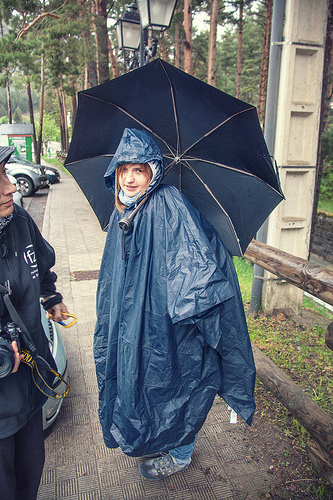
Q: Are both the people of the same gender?
A: No, they are both male and female.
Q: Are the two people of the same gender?
A: No, they are both male and female.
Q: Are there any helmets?
A: No, there are no helmets.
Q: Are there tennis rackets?
A: No, there are no tennis rackets.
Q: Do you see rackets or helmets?
A: No, there are no rackets or helmets.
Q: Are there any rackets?
A: No, there are no rackets.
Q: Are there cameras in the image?
A: Yes, there is a camera.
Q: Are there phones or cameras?
A: Yes, there is a camera.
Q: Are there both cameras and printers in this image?
A: No, there is a camera but no printers.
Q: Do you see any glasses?
A: No, there are no glasses.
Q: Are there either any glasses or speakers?
A: No, there are no glasses or speakers.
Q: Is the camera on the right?
A: No, the camera is on the left of the image.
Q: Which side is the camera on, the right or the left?
A: The camera is on the left of the image.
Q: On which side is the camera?
A: The camera is on the left of the image.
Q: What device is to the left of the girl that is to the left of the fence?
A: The device is a camera.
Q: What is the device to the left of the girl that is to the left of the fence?
A: The device is a camera.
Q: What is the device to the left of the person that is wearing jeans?
A: The device is a camera.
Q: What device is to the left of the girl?
A: The device is a camera.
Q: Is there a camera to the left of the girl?
A: Yes, there is a camera to the left of the girl.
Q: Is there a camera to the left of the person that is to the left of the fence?
A: Yes, there is a camera to the left of the girl.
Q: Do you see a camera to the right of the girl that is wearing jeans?
A: No, the camera is to the left of the girl.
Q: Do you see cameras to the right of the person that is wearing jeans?
A: No, the camera is to the left of the girl.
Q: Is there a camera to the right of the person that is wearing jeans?
A: No, the camera is to the left of the girl.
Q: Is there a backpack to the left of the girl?
A: No, there is a camera to the left of the girl.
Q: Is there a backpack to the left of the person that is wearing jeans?
A: No, there is a camera to the left of the girl.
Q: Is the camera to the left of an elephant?
A: No, the camera is to the left of a girl.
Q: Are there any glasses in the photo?
A: No, there are no glasses.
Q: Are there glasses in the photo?
A: No, there are no glasses.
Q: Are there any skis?
A: No, there are no skis.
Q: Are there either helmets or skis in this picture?
A: No, there are no skis or helmets.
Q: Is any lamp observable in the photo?
A: Yes, there is a lamp.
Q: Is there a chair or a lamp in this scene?
A: Yes, there is a lamp.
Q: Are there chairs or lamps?
A: Yes, there is a lamp.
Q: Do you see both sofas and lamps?
A: No, there is a lamp but no sofas.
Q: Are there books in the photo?
A: No, there are no books.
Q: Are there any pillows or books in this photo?
A: No, there are no books or pillows.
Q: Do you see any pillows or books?
A: No, there are no books or pillows.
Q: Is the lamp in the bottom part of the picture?
A: No, the lamp is in the top of the image.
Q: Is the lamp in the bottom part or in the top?
A: The lamp is in the top of the image.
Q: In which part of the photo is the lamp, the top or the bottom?
A: The lamp is in the top of the image.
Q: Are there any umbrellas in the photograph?
A: Yes, there is an umbrella.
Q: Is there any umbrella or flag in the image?
A: Yes, there is an umbrella.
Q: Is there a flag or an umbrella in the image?
A: Yes, there is an umbrella.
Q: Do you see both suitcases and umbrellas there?
A: No, there is an umbrella but no suitcases.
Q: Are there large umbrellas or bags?
A: Yes, there is a large umbrella.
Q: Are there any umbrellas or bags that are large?
A: Yes, the umbrella is large.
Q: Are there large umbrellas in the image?
A: Yes, there is a large umbrella.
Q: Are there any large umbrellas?
A: Yes, there is a large umbrella.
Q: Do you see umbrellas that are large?
A: Yes, there is a large umbrella.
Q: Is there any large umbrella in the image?
A: Yes, there is a large umbrella.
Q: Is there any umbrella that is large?
A: Yes, there is an umbrella that is large.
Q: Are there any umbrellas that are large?
A: Yes, there is an umbrella that is large.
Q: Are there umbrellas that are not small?
A: Yes, there is a large umbrella.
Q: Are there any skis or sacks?
A: No, there are no skis or sacks.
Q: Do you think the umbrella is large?
A: Yes, the umbrella is large.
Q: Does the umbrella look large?
A: Yes, the umbrella is large.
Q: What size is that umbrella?
A: The umbrella is large.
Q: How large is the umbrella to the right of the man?
A: The umbrella is large.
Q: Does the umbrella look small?
A: No, the umbrella is large.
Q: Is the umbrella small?
A: No, the umbrella is large.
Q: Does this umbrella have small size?
A: No, the umbrella is large.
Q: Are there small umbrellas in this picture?
A: No, there is an umbrella but it is large.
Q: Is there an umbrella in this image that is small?
A: No, there is an umbrella but it is large.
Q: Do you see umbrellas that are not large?
A: No, there is an umbrella but it is large.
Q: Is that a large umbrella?
A: Yes, that is a large umbrella.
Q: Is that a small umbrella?
A: No, that is a large umbrella.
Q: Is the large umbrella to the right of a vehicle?
A: Yes, the umbrella is to the right of a vehicle.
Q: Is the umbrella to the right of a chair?
A: No, the umbrella is to the right of a vehicle.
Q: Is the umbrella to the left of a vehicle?
A: No, the umbrella is to the right of a vehicle.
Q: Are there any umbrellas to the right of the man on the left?
A: Yes, there is an umbrella to the right of the man.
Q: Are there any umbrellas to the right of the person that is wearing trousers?
A: Yes, there is an umbrella to the right of the man.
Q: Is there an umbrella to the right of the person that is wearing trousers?
A: Yes, there is an umbrella to the right of the man.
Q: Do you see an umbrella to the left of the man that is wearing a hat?
A: No, the umbrella is to the right of the man.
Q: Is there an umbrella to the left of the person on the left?
A: No, the umbrella is to the right of the man.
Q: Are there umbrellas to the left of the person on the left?
A: No, the umbrella is to the right of the man.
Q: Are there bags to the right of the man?
A: No, there is an umbrella to the right of the man.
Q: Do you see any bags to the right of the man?
A: No, there is an umbrella to the right of the man.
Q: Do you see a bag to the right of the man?
A: No, there is an umbrella to the right of the man.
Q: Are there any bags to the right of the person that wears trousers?
A: No, there is an umbrella to the right of the man.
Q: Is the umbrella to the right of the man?
A: Yes, the umbrella is to the right of the man.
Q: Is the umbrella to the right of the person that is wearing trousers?
A: Yes, the umbrella is to the right of the man.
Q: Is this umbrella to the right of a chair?
A: No, the umbrella is to the right of the man.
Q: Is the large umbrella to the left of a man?
A: No, the umbrella is to the right of a man.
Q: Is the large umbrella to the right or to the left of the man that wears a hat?
A: The umbrella is to the right of the man.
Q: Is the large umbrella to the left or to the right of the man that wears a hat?
A: The umbrella is to the right of the man.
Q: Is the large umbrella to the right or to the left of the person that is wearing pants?
A: The umbrella is to the right of the man.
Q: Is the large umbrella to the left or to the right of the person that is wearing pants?
A: The umbrella is to the right of the man.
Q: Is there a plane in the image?
A: No, there are no airplanes.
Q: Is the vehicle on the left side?
A: Yes, the vehicle is on the left of the image.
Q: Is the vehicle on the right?
A: No, the vehicle is on the left of the image.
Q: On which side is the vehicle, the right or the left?
A: The vehicle is on the left of the image.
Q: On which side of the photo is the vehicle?
A: The vehicle is on the left of the image.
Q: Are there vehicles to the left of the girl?
A: Yes, there is a vehicle to the left of the girl.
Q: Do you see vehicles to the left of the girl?
A: Yes, there is a vehicle to the left of the girl.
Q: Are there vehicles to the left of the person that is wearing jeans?
A: Yes, there is a vehicle to the left of the girl.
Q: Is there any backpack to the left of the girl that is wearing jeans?
A: No, there is a vehicle to the left of the girl.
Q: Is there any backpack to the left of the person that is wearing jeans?
A: No, there is a vehicle to the left of the girl.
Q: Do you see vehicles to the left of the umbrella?
A: Yes, there is a vehicle to the left of the umbrella.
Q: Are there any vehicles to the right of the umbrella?
A: No, the vehicle is to the left of the umbrella.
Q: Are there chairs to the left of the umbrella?
A: No, there is a vehicle to the left of the umbrella.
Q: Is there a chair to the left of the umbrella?
A: No, there is a vehicle to the left of the umbrella.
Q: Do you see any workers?
A: No, there are no workers.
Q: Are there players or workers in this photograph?
A: No, there are no workers or players.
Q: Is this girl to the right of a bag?
A: No, the girl is to the right of a vehicle.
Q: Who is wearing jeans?
A: The girl is wearing jeans.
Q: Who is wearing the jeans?
A: The girl is wearing jeans.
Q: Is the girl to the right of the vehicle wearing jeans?
A: Yes, the girl is wearing jeans.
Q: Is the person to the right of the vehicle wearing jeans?
A: Yes, the girl is wearing jeans.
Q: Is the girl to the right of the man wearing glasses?
A: No, the girl is wearing jeans.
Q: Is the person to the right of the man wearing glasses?
A: No, the girl is wearing jeans.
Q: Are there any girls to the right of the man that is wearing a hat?
A: Yes, there is a girl to the right of the man.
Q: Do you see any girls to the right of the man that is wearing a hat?
A: Yes, there is a girl to the right of the man.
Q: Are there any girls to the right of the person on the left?
A: Yes, there is a girl to the right of the man.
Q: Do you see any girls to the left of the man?
A: No, the girl is to the right of the man.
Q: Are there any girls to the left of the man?
A: No, the girl is to the right of the man.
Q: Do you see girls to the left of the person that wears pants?
A: No, the girl is to the right of the man.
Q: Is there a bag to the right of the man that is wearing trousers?
A: No, there is a girl to the right of the man.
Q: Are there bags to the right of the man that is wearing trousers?
A: No, there is a girl to the right of the man.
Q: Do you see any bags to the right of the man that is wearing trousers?
A: No, there is a girl to the right of the man.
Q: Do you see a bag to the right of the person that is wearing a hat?
A: No, there is a girl to the right of the man.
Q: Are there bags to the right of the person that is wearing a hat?
A: No, there is a girl to the right of the man.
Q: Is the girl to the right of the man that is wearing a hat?
A: Yes, the girl is to the right of the man.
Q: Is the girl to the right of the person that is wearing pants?
A: Yes, the girl is to the right of the man.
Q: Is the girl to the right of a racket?
A: No, the girl is to the right of the man.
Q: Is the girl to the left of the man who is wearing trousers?
A: No, the girl is to the right of the man.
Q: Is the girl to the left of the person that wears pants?
A: No, the girl is to the right of the man.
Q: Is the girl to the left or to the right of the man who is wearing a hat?
A: The girl is to the right of the man.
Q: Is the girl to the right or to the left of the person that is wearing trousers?
A: The girl is to the right of the man.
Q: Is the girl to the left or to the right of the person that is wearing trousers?
A: The girl is to the right of the man.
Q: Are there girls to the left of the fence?
A: Yes, there is a girl to the left of the fence.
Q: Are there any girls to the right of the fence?
A: No, the girl is to the left of the fence.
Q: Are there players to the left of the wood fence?
A: No, there is a girl to the left of the fence.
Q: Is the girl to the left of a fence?
A: Yes, the girl is to the left of a fence.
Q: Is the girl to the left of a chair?
A: No, the girl is to the left of a fence.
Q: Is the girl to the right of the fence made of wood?
A: No, the girl is to the left of the fence.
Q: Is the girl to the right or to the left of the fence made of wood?
A: The girl is to the left of the fence.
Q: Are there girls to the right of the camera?
A: Yes, there is a girl to the right of the camera.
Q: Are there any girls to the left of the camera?
A: No, the girl is to the right of the camera.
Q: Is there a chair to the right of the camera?
A: No, there is a girl to the right of the camera.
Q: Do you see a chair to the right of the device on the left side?
A: No, there is a girl to the right of the camera.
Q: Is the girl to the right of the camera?
A: Yes, the girl is to the right of the camera.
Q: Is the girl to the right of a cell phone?
A: No, the girl is to the right of the camera.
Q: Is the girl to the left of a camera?
A: No, the girl is to the right of a camera.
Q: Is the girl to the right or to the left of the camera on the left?
A: The girl is to the right of the camera.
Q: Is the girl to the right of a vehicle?
A: Yes, the girl is to the right of a vehicle.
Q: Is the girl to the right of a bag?
A: No, the girl is to the right of a vehicle.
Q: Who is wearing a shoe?
A: The girl is wearing a shoe.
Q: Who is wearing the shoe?
A: The girl is wearing a shoe.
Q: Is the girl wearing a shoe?
A: Yes, the girl is wearing a shoe.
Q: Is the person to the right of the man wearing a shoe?
A: Yes, the girl is wearing a shoe.